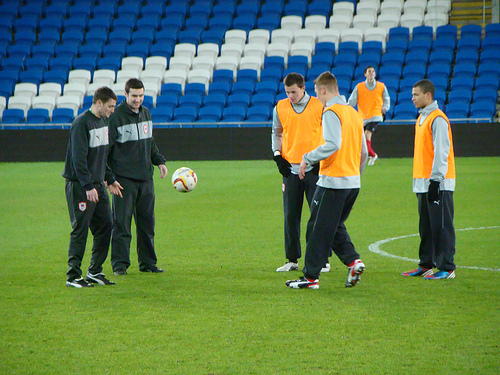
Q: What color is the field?
A: Green.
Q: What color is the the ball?
A: White and red.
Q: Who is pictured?
A: Players.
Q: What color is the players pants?
A: Black.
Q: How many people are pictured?
A: 6.